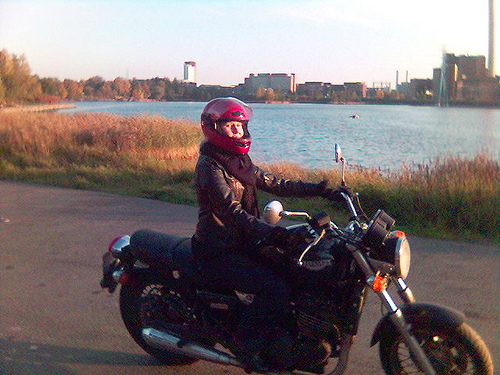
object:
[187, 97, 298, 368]
person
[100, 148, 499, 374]
motorcycle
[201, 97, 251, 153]
helmet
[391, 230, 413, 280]
headlight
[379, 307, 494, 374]
front tire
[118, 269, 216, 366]
rear tire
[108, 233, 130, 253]
brake light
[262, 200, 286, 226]
mirror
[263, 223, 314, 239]
handlebars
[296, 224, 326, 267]
turn signal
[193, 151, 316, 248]
jacket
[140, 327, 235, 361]
exhaust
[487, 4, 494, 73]
smokestack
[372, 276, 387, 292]
light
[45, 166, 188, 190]
grass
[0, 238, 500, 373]
road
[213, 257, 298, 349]
jeans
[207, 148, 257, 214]
scarf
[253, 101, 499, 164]
lake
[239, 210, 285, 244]
gloves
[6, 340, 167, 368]
shadow